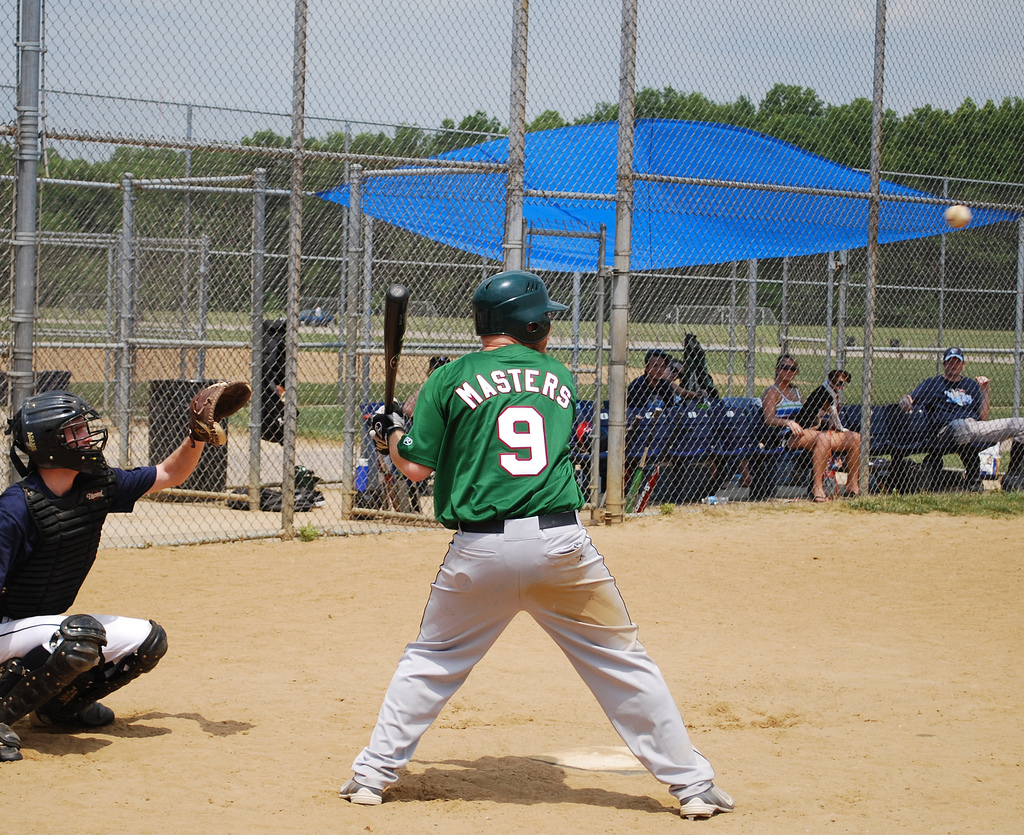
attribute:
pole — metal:
[273, 4, 306, 532]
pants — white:
[348, 503, 718, 798]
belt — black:
[449, 508, 583, 537]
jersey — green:
[407, 342, 578, 519]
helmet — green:
[475, 272, 570, 337]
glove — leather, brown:
[183, 374, 253, 438]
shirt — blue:
[3, 453, 162, 624]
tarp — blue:
[317, 110, 1022, 272]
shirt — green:
[430, 348, 599, 517]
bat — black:
[357, 269, 412, 435]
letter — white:
[446, 354, 486, 419]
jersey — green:
[417, 345, 598, 542]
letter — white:
[471, 368, 503, 394]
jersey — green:
[423, 352, 600, 549]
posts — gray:
[558, 88, 719, 512]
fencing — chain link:
[560, 142, 1006, 518]